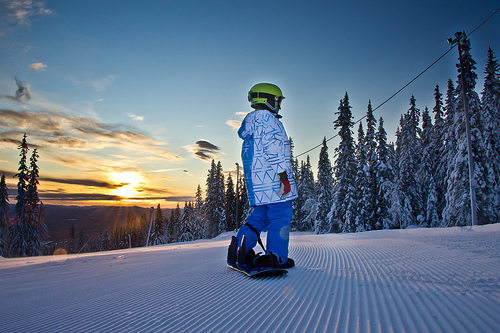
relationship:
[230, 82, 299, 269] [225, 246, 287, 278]
person on snowboard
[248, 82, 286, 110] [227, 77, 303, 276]
yellow helmet on person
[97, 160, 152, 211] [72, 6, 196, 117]
sun in sky